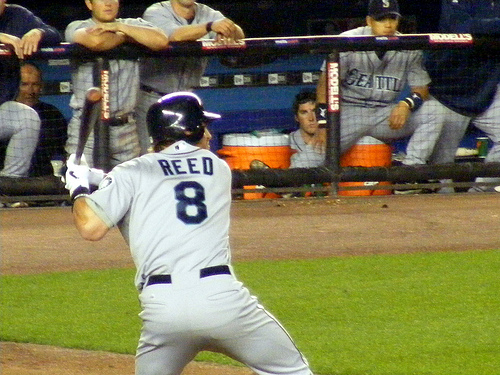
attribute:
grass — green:
[0, 247, 499, 374]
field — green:
[0, 192, 499, 374]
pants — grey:
[133, 264, 315, 374]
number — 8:
[174, 180, 209, 225]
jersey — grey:
[86, 140, 232, 291]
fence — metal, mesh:
[1, 33, 499, 208]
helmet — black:
[145, 91, 221, 144]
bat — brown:
[74, 89, 101, 164]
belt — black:
[144, 264, 232, 287]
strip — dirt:
[2, 190, 498, 270]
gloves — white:
[64, 152, 107, 200]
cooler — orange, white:
[215, 132, 296, 200]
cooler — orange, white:
[336, 136, 393, 198]